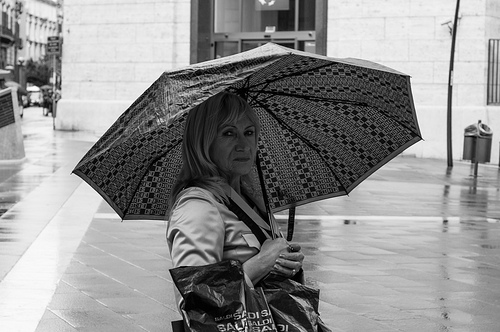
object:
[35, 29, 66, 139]
signs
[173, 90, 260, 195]
blonde hair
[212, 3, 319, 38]
window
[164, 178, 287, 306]
shirt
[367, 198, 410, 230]
ground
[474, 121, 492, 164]
garbage bin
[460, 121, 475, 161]
garbage bin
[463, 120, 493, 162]
trash can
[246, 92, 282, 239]
umbrella handle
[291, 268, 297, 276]
ring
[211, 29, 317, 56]
doors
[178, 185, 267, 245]
strap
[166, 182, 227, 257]
shoulder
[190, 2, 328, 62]
doorway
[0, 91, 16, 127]
black sign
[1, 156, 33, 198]
cement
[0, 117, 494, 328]
streets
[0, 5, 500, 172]
building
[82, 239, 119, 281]
pattern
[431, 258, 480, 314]
pattern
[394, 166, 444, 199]
pattern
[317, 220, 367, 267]
pattern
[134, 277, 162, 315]
pattern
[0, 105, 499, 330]
walk way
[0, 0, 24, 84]
building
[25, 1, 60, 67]
building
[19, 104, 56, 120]
street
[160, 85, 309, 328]
woman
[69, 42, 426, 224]
umbrella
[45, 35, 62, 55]
sign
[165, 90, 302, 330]
lady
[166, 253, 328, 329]
shopping bags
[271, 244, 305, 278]
hand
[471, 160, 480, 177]
pole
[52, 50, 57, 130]
pole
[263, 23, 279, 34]
sign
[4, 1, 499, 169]
background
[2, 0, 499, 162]
distance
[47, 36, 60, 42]
signs